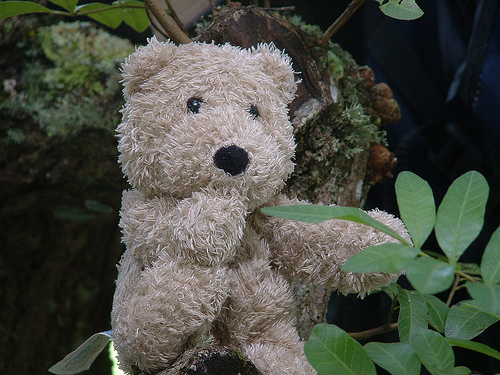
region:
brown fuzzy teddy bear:
[101, 28, 359, 373]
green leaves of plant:
[261, 188, 497, 371]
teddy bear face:
[105, 21, 325, 230]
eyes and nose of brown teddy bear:
[176, 82, 284, 194]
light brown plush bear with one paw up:
[97, 20, 399, 374]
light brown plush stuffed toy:
[107, 34, 400, 374]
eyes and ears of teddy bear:
[115, 18, 312, 130]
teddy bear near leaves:
[122, 33, 446, 371]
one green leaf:
[383, 153, 443, 263]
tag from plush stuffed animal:
[33, 307, 130, 374]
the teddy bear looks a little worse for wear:
[98, 35, 420, 372]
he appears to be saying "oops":
[113, 46, 359, 371]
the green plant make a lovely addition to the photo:
[289, 188, 496, 373]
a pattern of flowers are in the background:
[46, 73, 109, 215]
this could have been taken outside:
[1, 18, 486, 367]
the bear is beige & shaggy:
[117, 37, 409, 374]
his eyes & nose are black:
[168, 85, 281, 177]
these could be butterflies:
[343, 53, 410, 197]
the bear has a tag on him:
[38, 315, 123, 372]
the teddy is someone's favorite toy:
[108, 36, 388, 371]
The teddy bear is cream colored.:
[107, 27, 409, 374]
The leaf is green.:
[388, 158, 440, 256]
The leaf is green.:
[434, 161, 493, 268]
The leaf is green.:
[256, 197, 411, 238]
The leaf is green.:
[335, 236, 419, 282]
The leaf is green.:
[403, 250, 460, 301]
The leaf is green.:
[295, 317, 377, 374]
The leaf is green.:
[392, 283, 432, 345]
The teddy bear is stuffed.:
[108, 28, 415, 373]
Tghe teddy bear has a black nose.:
[98, 26, 412, 373]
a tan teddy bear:
[93, 32, 340, 371]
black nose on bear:
[208, 130, 244, 168]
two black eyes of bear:
[181, 89, 296, 129]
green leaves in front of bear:
[261, 189, 482, 367]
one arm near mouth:
[111, 168, 264, 270]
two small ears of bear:
[103, 23, 324, 102]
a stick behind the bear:
[146, 1, 184, 40]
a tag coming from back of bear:
[37, 310, 130, 372]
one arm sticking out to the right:
[258, 195, 432, 302]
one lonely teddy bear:
[86, 25, 381, 372]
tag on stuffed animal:
[36, 306, 132, 374]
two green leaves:
[386, 161, 496, 263]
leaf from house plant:
[251, 186, 410, 246]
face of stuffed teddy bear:
[107, 28, 310, 212]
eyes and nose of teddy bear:
[176, 83, 290, 190]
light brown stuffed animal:
[107, 32, 377, 374]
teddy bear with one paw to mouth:
[116, 24, 326, 374]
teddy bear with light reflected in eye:
[108, 29, 315, 231]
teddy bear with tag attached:
[48, 33, 349, 370]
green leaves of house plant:
[340, 163, 495, 339]